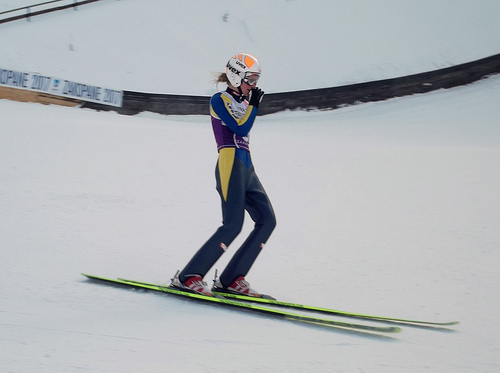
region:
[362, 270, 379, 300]
the snow is white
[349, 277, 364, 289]
the snow is white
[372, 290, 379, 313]
the snow is white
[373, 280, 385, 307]
the snow is white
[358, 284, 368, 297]
the snow is white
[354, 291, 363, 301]
the snow is white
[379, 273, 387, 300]
the snow is white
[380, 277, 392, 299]
the snow is white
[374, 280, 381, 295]
the snow is white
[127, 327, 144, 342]
the snow is white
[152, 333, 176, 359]
the snow is white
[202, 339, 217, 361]
the snow is white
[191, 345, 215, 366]
the snow is white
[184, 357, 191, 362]
the snow is white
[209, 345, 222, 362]
the snow is white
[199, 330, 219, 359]
the snow is white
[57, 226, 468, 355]
The skis are green.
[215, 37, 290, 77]
The person is wearing a helmet.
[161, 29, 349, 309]
The person is standing on skis.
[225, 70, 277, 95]
The person is wearing goggles.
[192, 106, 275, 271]
The jumper is blue and yellow.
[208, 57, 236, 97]
Hair hanging from the back of the helmet.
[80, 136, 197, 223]
The snow is white.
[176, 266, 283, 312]
The shoes are red and white.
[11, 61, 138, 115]
A sign is posted on the gate.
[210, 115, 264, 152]
The top is purple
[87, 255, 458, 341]
black and neon green skiis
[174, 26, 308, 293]
woman wearing skiing outfit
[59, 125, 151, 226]
smooth white snow on ground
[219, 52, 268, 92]
orange and white helmet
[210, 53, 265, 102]
woman wearing helmet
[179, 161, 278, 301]
yellow and black pants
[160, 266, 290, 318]
white and red shoes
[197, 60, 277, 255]
woman wearing skiing shoes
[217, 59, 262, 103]
woman with hand to mouth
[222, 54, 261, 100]
woman wearing goggles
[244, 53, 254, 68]
orange shape on white helmet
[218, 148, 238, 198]
yellow triangle on pants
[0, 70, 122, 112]
white banner behind skier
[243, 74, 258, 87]
skier wearing ski goggles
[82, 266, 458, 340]
skier on two yellow skis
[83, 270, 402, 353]
ski next to ski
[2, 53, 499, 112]
black divider behind skier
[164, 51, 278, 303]
skier is standing on skis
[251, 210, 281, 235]
knee is bent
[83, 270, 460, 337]
skis on snow